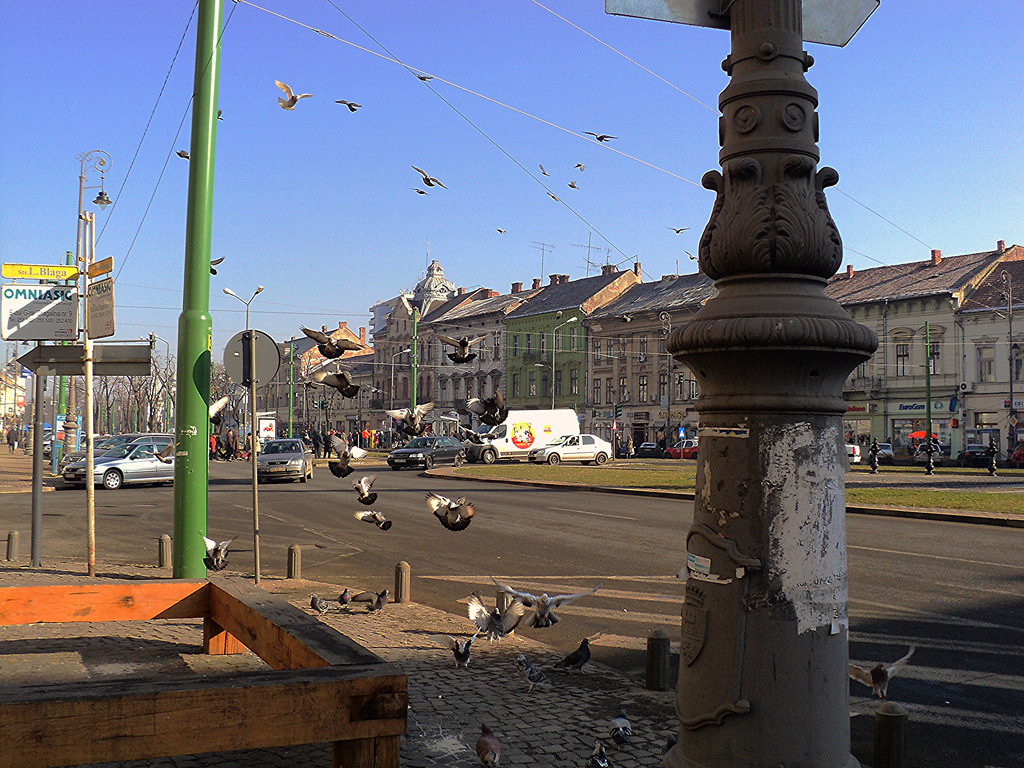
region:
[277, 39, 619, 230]
birds in the air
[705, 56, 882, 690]
gray post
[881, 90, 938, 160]
white clouds in blue sky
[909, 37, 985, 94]
white clouds in blue sky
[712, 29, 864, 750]
brown post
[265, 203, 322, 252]
white clouds in blue sky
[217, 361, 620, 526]
many cars on street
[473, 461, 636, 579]
street under the birds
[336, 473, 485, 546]
birds in a group flying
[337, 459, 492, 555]
birds in a group flying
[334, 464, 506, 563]
birds in a group flying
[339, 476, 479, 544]
birds in a group flying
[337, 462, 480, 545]
birds in a group flying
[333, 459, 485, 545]
birds in a group flying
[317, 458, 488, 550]
birds in a group flying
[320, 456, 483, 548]
birds in a group flying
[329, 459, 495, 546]
birds in a group flying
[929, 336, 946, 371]
A window on a building.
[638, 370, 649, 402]
A window on a building.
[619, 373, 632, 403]
A window on a building.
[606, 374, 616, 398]
A window on a building.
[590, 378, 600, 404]
A window on a building.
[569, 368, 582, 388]
A window on a building.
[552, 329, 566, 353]
A window on a building.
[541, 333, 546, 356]
A window on a building.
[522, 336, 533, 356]
A window on a building.